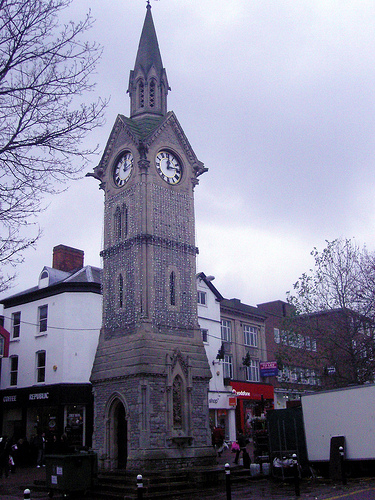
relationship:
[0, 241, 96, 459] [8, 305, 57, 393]
building has windows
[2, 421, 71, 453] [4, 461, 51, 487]
people on sidewalk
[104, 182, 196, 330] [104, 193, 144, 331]
lights are in front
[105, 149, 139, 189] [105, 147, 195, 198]
clock on top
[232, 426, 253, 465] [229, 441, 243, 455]
person holding bag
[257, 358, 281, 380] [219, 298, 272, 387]
sign on building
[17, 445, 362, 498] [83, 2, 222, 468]
posts protect tower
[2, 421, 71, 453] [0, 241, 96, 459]
people outside store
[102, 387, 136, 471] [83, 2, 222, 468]
door on building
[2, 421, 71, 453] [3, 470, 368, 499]
people on ground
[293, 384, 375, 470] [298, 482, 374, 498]
structure next to street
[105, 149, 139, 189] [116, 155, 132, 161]
clock has numbers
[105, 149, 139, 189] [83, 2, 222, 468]
clock on structure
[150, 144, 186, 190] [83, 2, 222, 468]
clock on structure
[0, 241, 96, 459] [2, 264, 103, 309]
building has roof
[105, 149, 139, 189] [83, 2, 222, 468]
clock on tower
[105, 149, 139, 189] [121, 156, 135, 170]
clock has hands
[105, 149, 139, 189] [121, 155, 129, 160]
clock has number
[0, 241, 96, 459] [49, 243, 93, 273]
building has chimney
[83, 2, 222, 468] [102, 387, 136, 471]
tower has door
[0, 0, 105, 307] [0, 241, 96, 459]
tree by building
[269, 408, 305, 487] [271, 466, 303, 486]
trashbin can roll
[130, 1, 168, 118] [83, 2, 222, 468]
spire on clocktower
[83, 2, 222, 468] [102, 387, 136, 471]
clocktower has enterance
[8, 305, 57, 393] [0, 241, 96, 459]
windows on building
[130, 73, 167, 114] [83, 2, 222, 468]
window on clocktower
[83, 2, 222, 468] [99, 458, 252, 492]
clocktower has stairs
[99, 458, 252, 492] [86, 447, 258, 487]
stairs at bottom